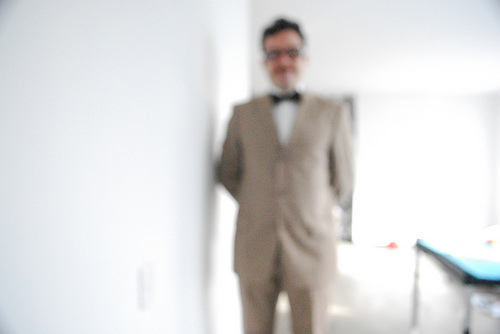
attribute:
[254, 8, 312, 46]
hair — dark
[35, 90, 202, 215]
wall — white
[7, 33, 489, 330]
scene — indoors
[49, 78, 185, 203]
wall — white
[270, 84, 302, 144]
shirt — white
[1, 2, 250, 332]
wall — white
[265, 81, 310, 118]
bow tie — black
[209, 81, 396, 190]
shirt — brown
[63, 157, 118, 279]
wall — white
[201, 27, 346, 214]
man — posing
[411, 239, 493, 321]
table — blue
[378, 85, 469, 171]
background — blurred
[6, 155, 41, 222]
section — small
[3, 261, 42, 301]
section — small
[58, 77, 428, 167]
section — small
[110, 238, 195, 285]
section — small